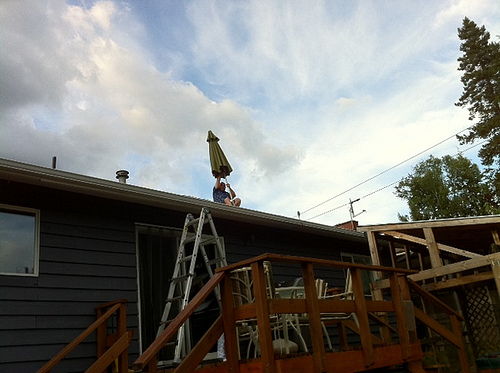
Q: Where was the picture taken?
A: In a back yard.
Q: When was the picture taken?
A: Daytime.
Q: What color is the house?
A: Gray.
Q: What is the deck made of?
A: Wood.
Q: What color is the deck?
A: Brown.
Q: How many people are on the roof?
A: One.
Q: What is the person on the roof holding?
A: An umbrella.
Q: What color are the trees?
A: Green.